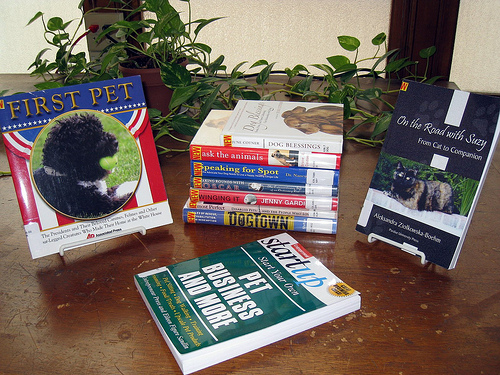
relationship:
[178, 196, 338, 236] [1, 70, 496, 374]
book on table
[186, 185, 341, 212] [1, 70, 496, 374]
book on table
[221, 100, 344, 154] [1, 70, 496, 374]
book on table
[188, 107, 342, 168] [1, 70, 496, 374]
book on table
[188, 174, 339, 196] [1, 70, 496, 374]
book on table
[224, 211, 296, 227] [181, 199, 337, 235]
yellow spine on book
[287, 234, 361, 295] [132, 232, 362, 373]
stickers on books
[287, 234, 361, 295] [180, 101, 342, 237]
stickers on books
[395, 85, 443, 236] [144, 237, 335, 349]
book on labels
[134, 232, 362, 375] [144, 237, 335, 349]
book on labels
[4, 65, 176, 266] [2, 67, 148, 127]
book has top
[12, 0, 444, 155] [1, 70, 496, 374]
leaves on table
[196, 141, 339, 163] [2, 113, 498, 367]
book on table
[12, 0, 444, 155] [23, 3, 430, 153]
leaves has leaves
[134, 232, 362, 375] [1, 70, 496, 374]
book stacked on table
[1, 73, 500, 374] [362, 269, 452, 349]
table has marks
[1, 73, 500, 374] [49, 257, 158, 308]
table has scratches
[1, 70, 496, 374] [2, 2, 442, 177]
table has leaves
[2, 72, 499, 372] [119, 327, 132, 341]
surface has spot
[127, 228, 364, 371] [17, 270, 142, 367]
book laying on table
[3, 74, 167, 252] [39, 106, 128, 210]
book cover has dog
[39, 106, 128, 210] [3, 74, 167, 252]
dog on book cover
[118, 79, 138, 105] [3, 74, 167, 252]
letter t on book cover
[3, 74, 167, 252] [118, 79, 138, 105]
book cover has letter t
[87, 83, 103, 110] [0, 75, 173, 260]
letter p on book cover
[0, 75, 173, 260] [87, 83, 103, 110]
book cover has letter p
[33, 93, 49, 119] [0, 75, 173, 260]
letter "r" on a book cover